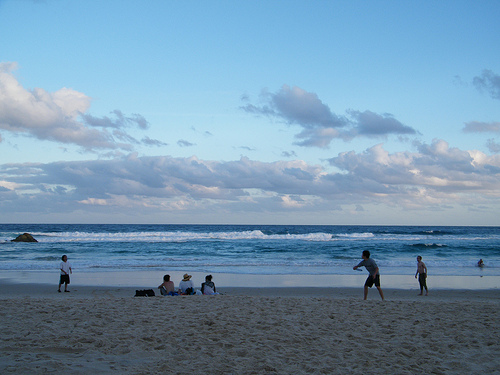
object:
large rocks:
[10, 232, 42, 244]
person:
[156, 273, 178, 296]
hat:
[180, 273, 193, 282]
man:
[350, 250, 383, 302]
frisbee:
[355, 267, 364, 272]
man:
[410, 254, 430, 298]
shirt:
[59, 261, 72, 274]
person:
[199, 274, 219, 295]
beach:
[0, 276, 499, 374]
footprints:
[152, 345, 169, 351]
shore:
[0, 268, 499, 291]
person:
[474, 258, 483, 270]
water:
[0, 221, 499, 292]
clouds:
[236, 86, 414, 149]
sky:
[0, 0, 499, 227]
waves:
[0, 228, 499, 258]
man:
[55, 253, 76, 295]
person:
[178, 273, 196, 296]